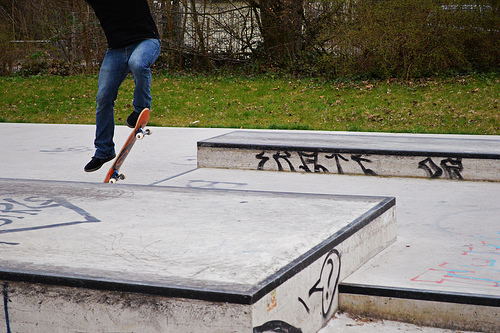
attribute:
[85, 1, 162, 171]
person — skateboarding, skating, a man, young, young man, doing a trick, performing a trick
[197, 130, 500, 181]
platform — large, for skateboarding, vast, cement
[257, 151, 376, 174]
graffiti — beautiful, painted, black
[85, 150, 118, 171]
shoe — black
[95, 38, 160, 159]
jeans — blue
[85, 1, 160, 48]
shirt — black, t shirt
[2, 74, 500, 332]
ground — gray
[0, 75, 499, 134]
grass — green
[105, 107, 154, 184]
skateboard — orange, in mid air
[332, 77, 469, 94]
leaves — dry, dead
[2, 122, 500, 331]
skatepark — skateboard use area, cement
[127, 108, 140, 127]
shoe — black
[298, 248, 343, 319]
graffiti — black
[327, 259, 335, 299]
question mark — graffiti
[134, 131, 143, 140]
wheel — white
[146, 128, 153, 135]
wheel — white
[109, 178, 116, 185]
wheel — white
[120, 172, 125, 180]
wheel — white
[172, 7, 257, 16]
branch — bare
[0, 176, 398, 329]
step — concrete